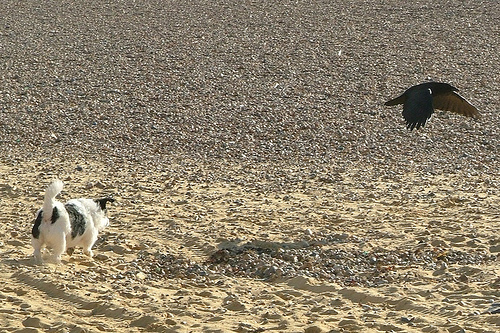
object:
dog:
[25, 176, 117, 270]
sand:
[2, 0, 499, 331]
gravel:
[1, 0, 500, 192]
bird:
[384, 80, 481, 132]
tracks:
[3, 176, 498, 331]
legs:
[29, 239, 46, 265]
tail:
[40, 179, 65, 223]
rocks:
[209, 223, 312, 286]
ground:
[0, 0, 500, 333]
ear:
[95, 197, 118, 213]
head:
[436, 83, 460, 95]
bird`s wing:
[432, 87, 481, 121]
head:
[89, 197, 115, 231]